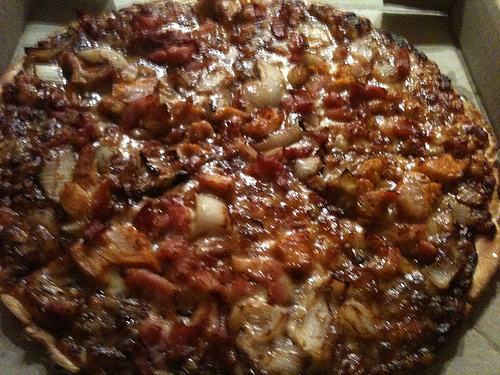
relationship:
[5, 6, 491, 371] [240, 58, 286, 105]
pizza has cheese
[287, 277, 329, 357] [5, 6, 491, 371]
onions on pizza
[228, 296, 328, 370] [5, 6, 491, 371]
onions on pizza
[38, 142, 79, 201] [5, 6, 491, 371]
onion on pizza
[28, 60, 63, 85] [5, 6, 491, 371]
onion on pizza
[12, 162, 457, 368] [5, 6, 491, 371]
bottom slice of pizza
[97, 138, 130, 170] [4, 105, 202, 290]
onion on pizza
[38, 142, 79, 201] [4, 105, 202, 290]
onion on pizza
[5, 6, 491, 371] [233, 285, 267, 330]
pizza seen part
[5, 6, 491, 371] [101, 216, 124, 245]
pizza seen part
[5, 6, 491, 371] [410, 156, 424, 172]
pizza seen part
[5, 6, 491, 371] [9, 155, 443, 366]
pizza seen part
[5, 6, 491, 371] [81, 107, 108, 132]
pizza seen part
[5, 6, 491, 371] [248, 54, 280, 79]
pizza seen part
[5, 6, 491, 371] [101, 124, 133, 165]
pizza seen part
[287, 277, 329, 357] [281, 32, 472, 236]
onions on pizza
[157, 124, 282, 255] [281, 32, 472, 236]
ham on pizza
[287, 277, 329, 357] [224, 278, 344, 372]
onions on area